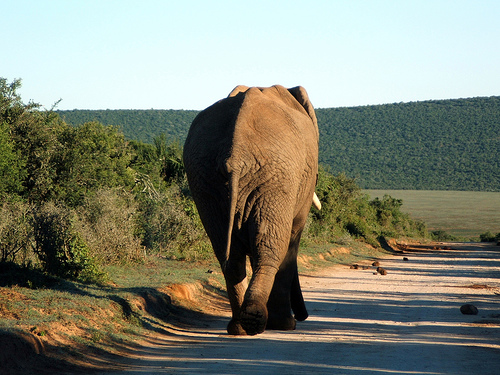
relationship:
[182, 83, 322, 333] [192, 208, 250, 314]
elephant has leg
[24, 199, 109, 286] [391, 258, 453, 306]
shrubs on side of road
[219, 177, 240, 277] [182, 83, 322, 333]
tail of elephant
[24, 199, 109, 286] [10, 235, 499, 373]
shrubs line path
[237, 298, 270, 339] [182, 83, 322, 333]
foot of elephant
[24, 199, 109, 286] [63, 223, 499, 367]
shrubs alongside path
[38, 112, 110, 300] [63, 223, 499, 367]
shrubs alongside path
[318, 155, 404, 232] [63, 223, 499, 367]
shrubs alongside path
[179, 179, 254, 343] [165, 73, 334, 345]
leg of elephant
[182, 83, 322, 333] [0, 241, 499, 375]
elephant walking on path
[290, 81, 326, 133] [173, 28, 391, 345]
ear of elephant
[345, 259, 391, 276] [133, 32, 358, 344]
dung of elephant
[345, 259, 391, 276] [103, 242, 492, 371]
dung in road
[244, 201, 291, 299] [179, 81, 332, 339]
leg of elephant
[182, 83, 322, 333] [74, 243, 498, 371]
elephant walking down a path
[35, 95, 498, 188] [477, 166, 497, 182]
hill has shrubs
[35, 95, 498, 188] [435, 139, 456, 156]
hill has shrubs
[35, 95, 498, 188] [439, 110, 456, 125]
hill has shrubs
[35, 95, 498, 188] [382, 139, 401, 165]
hill has shrubs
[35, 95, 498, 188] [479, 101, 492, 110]
hill has shrubs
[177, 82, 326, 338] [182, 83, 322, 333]
skin of an elephant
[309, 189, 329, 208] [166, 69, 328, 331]
tusk on elephant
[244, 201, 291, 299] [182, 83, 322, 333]
leg of elephant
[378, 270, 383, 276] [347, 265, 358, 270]
rocks on rocks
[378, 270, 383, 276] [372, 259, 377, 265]
rocks on rocks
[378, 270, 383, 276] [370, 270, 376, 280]
rocks on rocks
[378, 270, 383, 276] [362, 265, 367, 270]
rocks on rocks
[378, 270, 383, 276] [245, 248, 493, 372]
rocks on ground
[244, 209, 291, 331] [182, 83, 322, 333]
leg of elephant